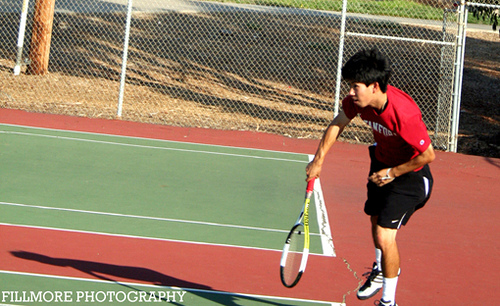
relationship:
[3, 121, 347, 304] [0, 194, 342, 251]
tennis court with white lines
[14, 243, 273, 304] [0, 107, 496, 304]
shadow on tennis court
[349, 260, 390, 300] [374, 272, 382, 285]
shoe with stripes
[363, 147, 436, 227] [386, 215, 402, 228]
shorts with logo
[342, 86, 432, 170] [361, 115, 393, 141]
t shirt with letters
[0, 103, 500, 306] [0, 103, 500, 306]
tennis court with tennis court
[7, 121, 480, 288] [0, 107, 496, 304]
red around tennis court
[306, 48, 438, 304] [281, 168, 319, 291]
he holding racquet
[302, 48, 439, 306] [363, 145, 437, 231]
he holding shorts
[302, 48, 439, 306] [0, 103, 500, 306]
he jumping off tennis court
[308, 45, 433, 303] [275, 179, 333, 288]
boy holding racquet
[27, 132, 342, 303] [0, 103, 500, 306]
white lines on tennis court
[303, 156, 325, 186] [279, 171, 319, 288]
hand holding racquet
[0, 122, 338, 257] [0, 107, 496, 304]
square patch on tennis court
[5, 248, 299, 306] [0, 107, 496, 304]
shadow on tennis court